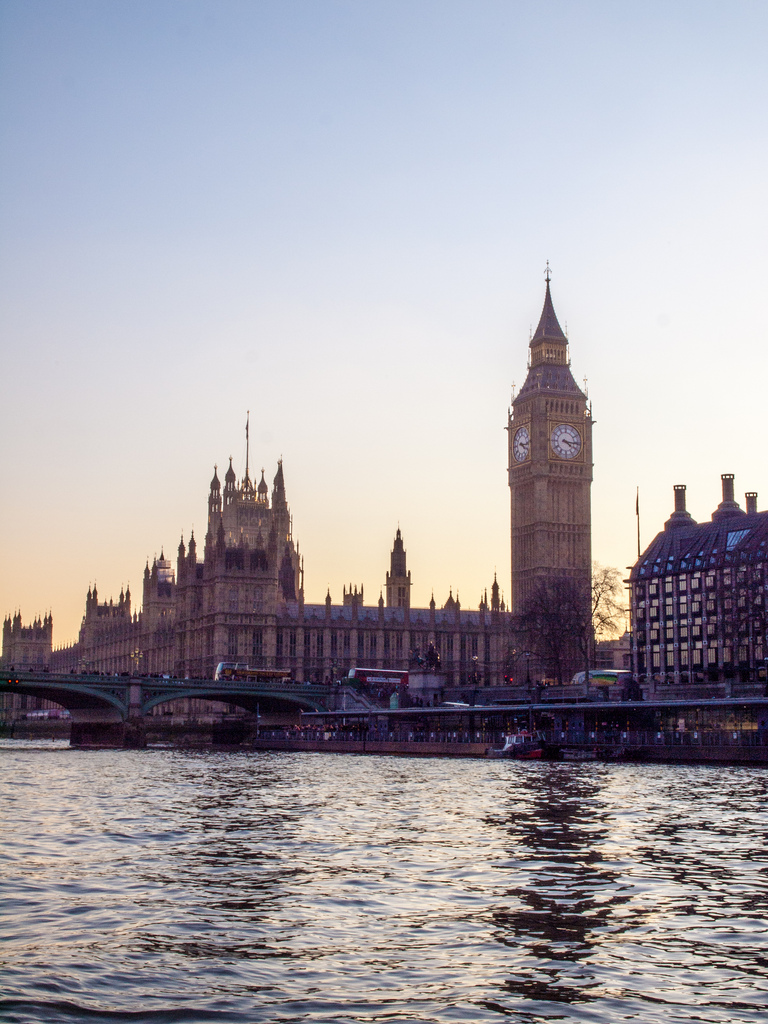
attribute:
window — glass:
[658, 573, 671, 591]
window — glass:
[633, 594, 646, 618]